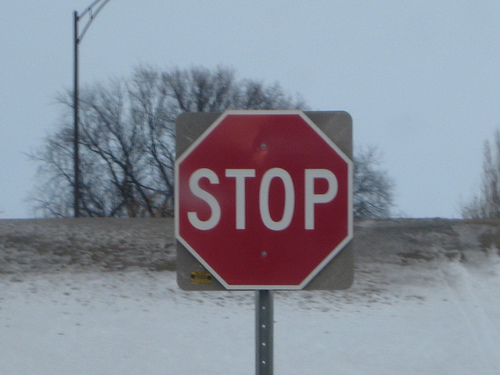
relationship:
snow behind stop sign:
[1, 270, 496, 375] [176, 110, 351, 289]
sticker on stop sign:
[189, 272, 216, 283] [176, 110, 351, 289]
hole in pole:
[261, 305, 266, 312] [254, 287, 275, 374]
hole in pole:
[260, 341, 266, 347] [254, 287, 275, 374]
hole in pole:
[261, 323, 268, 330] [254, 287, 275, 374]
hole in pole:
[260, 359, 269, 365] [254, 287, 275, 374]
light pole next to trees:
[74, 0, 110, 221] [27, 66, 398, 220]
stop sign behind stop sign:
[176, 110, 351, 289] [176, 110, 351, 289]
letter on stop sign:
[186, 167, 220, 231] [176, 110, 351, 289]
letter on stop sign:
[224, 168, 256, 232] [176, 110, 351, 289]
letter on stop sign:
[259, 167, 295, 232] [176, 110, 351, 289]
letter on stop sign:
[303, 168, 338, 231] [176, 110, 351, 289]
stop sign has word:
[176, 110, 351, 289] [187, 166, 338, 229]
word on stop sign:
[187, 166, 338, 229] [176, 110, 351, 289]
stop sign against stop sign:
[176, 110, 351, 289] [176, 110, 351, 289]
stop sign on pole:
[176, 110, 351, 289] [254, 287, 275, 374]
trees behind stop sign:
[27, 66, 398, 220] [176, 110, 351, 289]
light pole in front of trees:
[74, 0, 110, 221] [27, 66, 398, 220]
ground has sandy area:
[1, 215, 498, 374] [351, 217, 435, 271]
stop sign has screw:
[176, 110, 351, 289] [259, 142, 268, 149]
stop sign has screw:
[176, 110, 351, 289] [261, 251, 268, 258]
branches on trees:
[161, 68, 192, 111] [27, 66, 398, 220]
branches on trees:
[211, 63, 234, 107] [27, 66, 398, 220]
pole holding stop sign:
[254, 287, 275, 374] [176, 110, 351, 289]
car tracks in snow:
[432, 248, 500, 374] [1, 270, 496, 375]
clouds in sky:
[3, 0, 496, 121] [4, 2, 498, 217]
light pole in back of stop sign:
[74, 0, 110, 221] [176, 110, 351, 289]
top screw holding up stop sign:
[259, 142, 268, 149] [176, 110, 351, 289]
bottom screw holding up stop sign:
[263, 251, 268, 256] [176, 110, 351, 289]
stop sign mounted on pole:
[176, 110, 351, 289] [254, 287, 275, 374]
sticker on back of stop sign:
[189, 272, 216, 283] [176, 110, 351, 289]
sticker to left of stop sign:
[189, 272, 216, 283] [176, 110, 351, 289]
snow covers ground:
[1, 270, 496, 375] [1, 215, 498, 374]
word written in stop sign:
[187, 166, 338, 229] [176, 110, 351, 289]